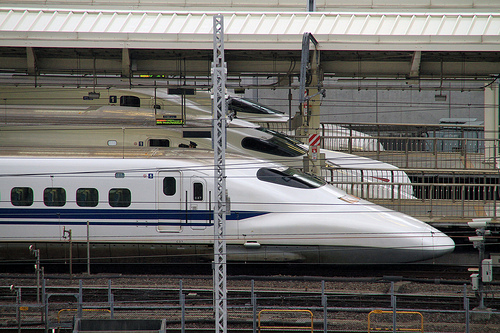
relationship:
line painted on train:
[0, 207, 271, 226] [0, 152, 462, 279]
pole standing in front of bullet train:
[204, 10, 236, 305] [1, 153, 456, 268]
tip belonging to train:
[387, 214, 453, 259] [0, 152, 462, 279]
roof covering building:
[0, 0, 500, 52] [1, 1, 484, 177]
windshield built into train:
[254, 158, 333, 194] [2, 138, 464, 283]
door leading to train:
[179, 167, 213, 232] [0, 152, 462, 279]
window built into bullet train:
[10, 186, 35, 205] [1, 153, 456, 268]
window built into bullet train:
[43, 187, 65, 207] [1, 153, 456, 268]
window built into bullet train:
[76, 188, 98, 206] [1, 153, 456, 268]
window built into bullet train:
[109, 189, 131, 206] [1, 153, 456, 268]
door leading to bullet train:
[182, 170, 208, 232] [1, 153, 456, 268]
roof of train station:
[3, 2, 488, 47] [0, 65, 495, 256]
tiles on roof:
[1, 0, 498, 52] [388, 4, 469, 54]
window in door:
[163, 175, 176, 196] [151, 165, 185, 241]